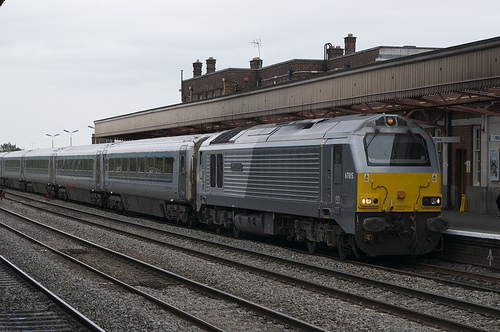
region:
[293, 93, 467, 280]
front of the train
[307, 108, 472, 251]
yellow and red train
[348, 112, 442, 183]
front of the window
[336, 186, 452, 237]
lights on the train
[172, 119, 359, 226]
side of the train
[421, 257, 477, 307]
track under the train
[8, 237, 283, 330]
tracks on the ground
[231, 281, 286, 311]
rocks on the ground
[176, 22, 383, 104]
roof of a building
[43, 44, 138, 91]
sky in the photo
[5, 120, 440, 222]
train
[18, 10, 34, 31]
white clouds in blue sky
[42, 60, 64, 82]
white clouds in blue sky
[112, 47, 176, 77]
white clouds in blue sky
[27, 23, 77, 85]
white clouds in blue sky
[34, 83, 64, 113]
white clouds in blue sky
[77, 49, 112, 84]
white clouds in blue sky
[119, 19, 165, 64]
white clouds in blue sky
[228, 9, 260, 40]
white clouds in blue sky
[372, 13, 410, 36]
white clouds in blue sky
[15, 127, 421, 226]
silver and yellow train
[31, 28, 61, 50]
white clouds in blue sky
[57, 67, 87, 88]
white clouds in blue sky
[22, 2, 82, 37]
white clouds in blue sky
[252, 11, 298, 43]
white clouds in blue sky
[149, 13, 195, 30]
white clouds in blue sky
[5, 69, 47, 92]
white clouds in blue sky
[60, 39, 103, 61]
white clouds in blue sky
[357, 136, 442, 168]
Small window on a train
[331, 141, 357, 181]
Small window on a train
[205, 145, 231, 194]
Small window on a train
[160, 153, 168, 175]
Small window on a train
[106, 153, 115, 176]
Small window on a train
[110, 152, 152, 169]
Small window on a train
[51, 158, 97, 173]
Small window on a train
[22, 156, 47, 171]
Small window on a train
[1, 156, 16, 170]
Small window on a train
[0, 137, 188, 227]
Large grey train carts oin track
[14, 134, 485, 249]
a train on the tracks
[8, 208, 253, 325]
the train tracks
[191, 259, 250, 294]
rocks next to the train tracks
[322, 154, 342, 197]
a door on the train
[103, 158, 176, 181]
windows on the train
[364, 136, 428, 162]
a windshield on the train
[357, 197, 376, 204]
a headlight on the train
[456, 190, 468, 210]
a yellow sign on the ground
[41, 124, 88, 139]
lights next to the train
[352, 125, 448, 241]
a yellow train